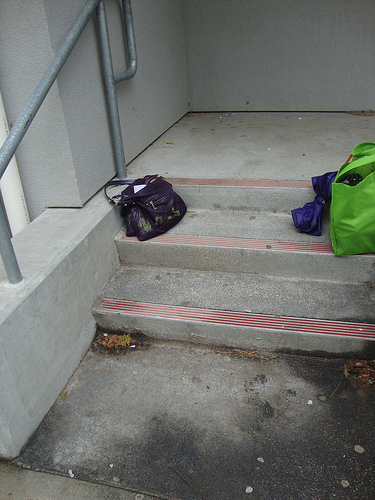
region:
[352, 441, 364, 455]
white spot on ground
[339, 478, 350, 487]
white spot on ground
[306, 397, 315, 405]
white spot on ground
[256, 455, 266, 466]
white spot on ground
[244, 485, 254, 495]
white spot on ground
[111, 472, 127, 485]
white spot on ground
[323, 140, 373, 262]
green tote bag on the stairs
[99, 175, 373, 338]
red tread on the stairs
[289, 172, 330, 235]
blue umbrella on the stairs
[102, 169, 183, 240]
black handbag on the stairs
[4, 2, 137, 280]
metal railing next to stairs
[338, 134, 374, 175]
green handles on the tote bag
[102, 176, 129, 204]
black strap on the bag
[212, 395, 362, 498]
gum stuck on pavement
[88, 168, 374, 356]
set of cement stairs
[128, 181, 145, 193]
paper in the bag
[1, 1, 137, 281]
two poles under metal railing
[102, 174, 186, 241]
purple purse with strap on cement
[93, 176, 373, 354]
red treads on cement stairs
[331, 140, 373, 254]
green fabric grocery bag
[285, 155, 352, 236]
closed tilted blue umbrella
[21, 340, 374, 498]
dark stain on gray cement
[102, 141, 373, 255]
three items on cement stair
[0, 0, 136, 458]
metal rail on cement wall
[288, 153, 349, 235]
tie around middle of umbrella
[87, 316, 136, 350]
debris in cement corner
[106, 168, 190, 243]
black purse with green paint stains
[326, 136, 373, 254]
large green bag sitting on grey concrete platform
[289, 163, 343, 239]
blue umbrella tied up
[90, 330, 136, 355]
small patch of grass growing in crevis of stairs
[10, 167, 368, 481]
concrete steps with red trim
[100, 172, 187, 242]
black purse resting on grey stairs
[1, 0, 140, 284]
silver metal stair railing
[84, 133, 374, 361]
steps with black purse, green bag and blue umbrella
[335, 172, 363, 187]
black item peeking from green bag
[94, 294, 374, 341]
red anti slip bars on grey steps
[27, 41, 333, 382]
these are small stairs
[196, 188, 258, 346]
the stairs are red and gray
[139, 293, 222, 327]
the red is metal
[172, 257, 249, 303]
the stairs are pavement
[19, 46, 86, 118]
the railing is gray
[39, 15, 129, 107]
the rail is metal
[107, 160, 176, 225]
the bag is a purse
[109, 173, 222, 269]
the bag is purple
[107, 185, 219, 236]
the bag has leather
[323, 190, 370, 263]
this is a green bag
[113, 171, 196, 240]
A purple purse sitting on a step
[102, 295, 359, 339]
A slip control marker on a cement step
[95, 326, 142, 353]
Some dirty leaves lying on the ground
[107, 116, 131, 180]
A short metal pole